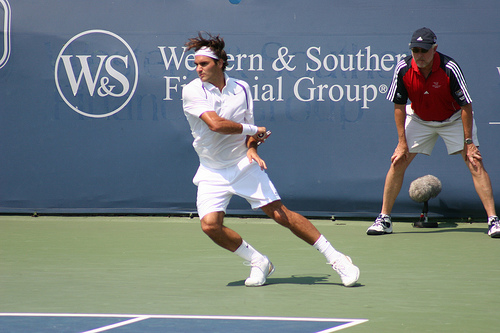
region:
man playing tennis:
[174, 35, 364, 294]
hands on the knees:
[383, 138, 488, 171]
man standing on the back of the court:
[359, 23, 499, 240]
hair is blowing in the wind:
[174, 30, 231, 53]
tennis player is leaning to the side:
[163, 30, 372, 290]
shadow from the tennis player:
[218, 270, 359, 290]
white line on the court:
[73, 318, 143, 332]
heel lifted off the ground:
[243, 253, 278, 293]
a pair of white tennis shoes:
[232, 252, 373, 288]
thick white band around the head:
[190, 42, 225, 62]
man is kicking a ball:
[173, 40, 333, 275]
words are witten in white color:
[49, 27, 116, 134]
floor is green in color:
[417, 269, 482, 331]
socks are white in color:
[303, 242, 345, 258]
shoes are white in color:
[326, 257, 369, 289]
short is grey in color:
[403, 109, 488, 158]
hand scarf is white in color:
[234, 115, 266, 134]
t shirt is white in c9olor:
[180, 102, 226, 154]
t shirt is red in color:
[395, 67, 473, 109]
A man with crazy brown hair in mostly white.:
[181, 32, 361, 287]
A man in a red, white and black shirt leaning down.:
[366, 29, 498, 236]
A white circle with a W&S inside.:
[55, 29, 139, 119]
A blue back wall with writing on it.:
[1, 1, 499, 219]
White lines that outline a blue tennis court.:
[1, 311, 371, 332]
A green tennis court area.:
[1, 212, 499, 331]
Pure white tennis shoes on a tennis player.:
[245, 254, 360, 286]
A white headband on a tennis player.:
[194, 46, 219, 61]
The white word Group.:
[294, 74, 377, 109]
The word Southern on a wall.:
[305, 45, 408, 72]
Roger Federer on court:
[134, 34, 359, 289]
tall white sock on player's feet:
[307, 235, 345, 260]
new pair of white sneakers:
[242, 261, 371, 296]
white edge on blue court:
[331, 306, 370, 327]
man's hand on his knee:
[373, 135, 493, 174]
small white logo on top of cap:
[401, 28, 435, 45]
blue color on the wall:
[12, 123, 100, 173]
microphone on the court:
[404, 169, 449, 213]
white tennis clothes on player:
[175, 77, 285, 227]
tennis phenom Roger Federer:
[175, 19, 367, 294]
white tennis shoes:
[243, 255, 365, 287]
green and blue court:
[4, 215, 234, 332]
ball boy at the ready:
[362, 24, 497, 250]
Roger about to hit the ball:
[172, 26, 366, 288]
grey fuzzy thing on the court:
[405, 172, 457, 231]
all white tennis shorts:
[190, 157, 285, 216]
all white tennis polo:
[180, 77, 258, 186]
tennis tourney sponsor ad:
[48, 25, 413, 122]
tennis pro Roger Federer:
[176, 30, 367, 292]